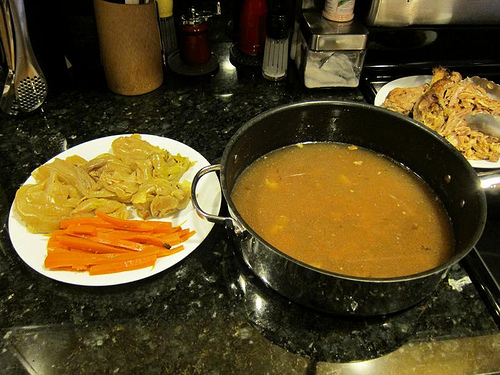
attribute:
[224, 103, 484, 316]
pot — black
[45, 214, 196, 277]
carrots — cooked, orange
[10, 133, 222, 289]
plate — white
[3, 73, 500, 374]
counter top — black, dark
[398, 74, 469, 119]
chicken — cooked, shredded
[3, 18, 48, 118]
utensils — silver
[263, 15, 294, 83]
shaker — glass, empty, salt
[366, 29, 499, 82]
stove — black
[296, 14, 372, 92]
container — glass, tea bags